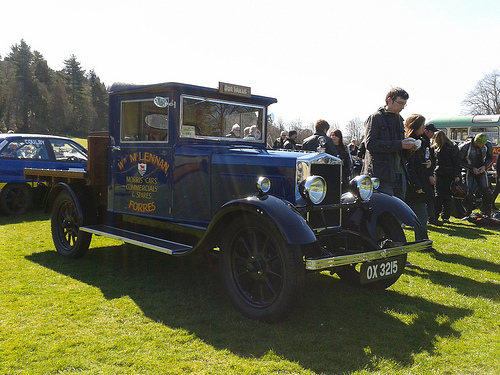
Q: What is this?
A: A car.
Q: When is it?
A: Daytime.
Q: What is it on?
A: Grass.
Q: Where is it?
A: At a car show.